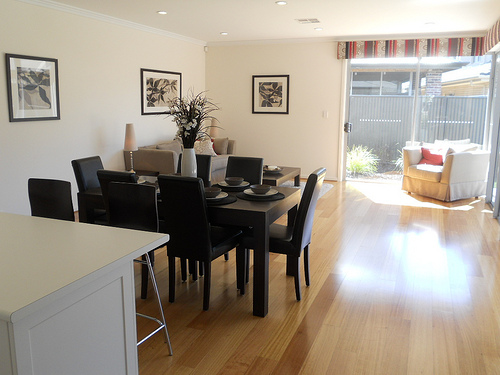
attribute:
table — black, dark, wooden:
[73, 170, 304, 325]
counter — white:
[1, 208, 177, 334]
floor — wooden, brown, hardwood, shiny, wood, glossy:
[49, 171, 498, 374]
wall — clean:
[204, 45, 346, 187]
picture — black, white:
[138, 65, 184, 116]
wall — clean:
[2, 1, 207, 219]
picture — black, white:
[4, 52, 63, 124]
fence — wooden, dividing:
[348, 93, 487, 178]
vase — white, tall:
[180, 148, 204, 181]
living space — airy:
[131, 26, 499, 209]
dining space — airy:
[4, 1, 335, 375]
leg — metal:
[145, 253, 178, 361]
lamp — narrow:
[122, 120, 140, 176]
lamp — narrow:
[210, 116, 220, 139]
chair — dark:
[238, 167, 330, 305]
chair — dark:
[154, 167, 246, 310]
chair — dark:
[223, 151, 268, 271]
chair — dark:
[96, 167, 189, 303]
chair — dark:
[70, 153, 123, 225]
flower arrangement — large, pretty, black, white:
[159, 85, 219, 153]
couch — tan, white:
[129, 127, 238, 177]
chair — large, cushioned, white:
[400, 136, 491, 205]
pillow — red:
[418, 142, 448, 168]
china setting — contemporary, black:
[242, 183, 280, 197]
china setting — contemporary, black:
[216, 175, 249, 190]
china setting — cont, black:
[199, 184, 229, 200]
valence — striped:
[331, 15, 500, 63]